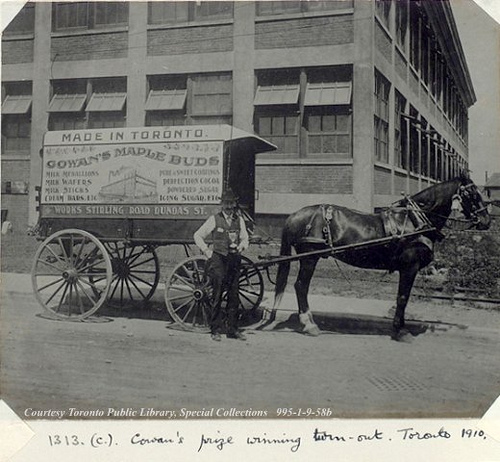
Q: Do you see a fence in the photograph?
A: No, there are no fences.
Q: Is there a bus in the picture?
A: No, there are no buses.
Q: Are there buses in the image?
A: No, there are no buses.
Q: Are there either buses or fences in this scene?
A: No, there are no buses or fences.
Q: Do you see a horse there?
A: Yes, there is a horse.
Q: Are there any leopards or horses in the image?
A: Yes, there is a horse.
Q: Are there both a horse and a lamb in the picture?
A: No, there is a horse but no lambs.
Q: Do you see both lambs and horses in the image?
A: No, there is a horse but no lambs.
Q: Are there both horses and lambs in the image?
A: No, there is a horse but no lambs.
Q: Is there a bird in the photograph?
A: No, there are no birds.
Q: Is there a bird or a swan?
A: No, there are no birds or swans.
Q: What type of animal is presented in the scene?
A: The animal is a horse.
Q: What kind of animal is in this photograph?
A: The animal is a horse.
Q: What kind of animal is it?
A: The animal is a horse.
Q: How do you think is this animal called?
A: This is a horse.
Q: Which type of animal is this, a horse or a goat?
A: This is a horse.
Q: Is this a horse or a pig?
A: This is a horse.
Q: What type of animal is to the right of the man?
A: The animal is a horse.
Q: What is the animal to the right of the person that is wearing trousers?
A: The animal is a horse.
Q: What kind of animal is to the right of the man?
A: The animal is a horse.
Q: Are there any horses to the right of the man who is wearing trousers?
A: Yes, there is a horse to the right of the man.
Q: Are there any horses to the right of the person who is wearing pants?
A: Yes, there is a horse to the right of the man.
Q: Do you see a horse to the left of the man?
A: No, the horse is to the right of the man.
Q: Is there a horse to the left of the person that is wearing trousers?
A: No, the horse is to the right of the man.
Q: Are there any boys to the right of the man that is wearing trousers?
A: No, there is a horse to the right of the man.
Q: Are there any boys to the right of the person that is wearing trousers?
A: No, there is a horse to the right of the man.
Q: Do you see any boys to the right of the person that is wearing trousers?
A: No, there is a horse to the right of the man.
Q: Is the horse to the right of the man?
A: Yes, the horse is to the right of the man.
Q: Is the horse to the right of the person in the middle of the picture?
A: Yes, the horse is to the right of the man.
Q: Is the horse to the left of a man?
A: No, the horse is to the right of a man.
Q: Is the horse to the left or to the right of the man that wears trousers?
A: The horse is to the right of the man.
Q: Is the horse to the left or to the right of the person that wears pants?
A: The horse is to the right of the man.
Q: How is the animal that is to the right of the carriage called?
A: The animal is a horse.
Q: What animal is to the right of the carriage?
A: The animal is a horse.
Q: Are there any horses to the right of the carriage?
A: Yes, there is a horse to the right of the carriage.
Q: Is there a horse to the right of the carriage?
A: Yes, there is a horse to the right of the carriage.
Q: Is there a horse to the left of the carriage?
A: No, the horse is to the right of the carriage.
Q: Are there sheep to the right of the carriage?
A: No, there is a horse to the right of the carriage.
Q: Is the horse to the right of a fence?
A: No, the horse is to the right of a carriage.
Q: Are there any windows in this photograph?
A: Yes, there is a window.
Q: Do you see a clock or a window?
A: Yes, there is a window.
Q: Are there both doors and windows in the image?
A: No, there is a window but no doors.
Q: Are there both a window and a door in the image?
A: No, there is a window but no doors.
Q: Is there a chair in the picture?
A: No, there are no chairs.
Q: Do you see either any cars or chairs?
A: No, there are no chairs or cars.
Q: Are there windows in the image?
A: Yes, there is a window.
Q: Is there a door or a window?
A: Yes, there is a window.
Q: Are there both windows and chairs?
A: No, there is a window but no chairs.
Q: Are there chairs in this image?
A: No, there are no chairs.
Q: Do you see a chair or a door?
A: No, there are no chairs or doors.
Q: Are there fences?
A: No, there are no fences.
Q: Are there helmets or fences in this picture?
A: No, there are no fences or helmets.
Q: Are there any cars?
A: No, there are no cars.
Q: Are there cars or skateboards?
A: No, there are no cars or skateboards.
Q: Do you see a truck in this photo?
A: No, there are no trucks.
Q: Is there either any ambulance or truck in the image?
A: No, there are no trucks or ambulances.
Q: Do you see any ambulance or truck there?
A: No, there are no trucks or ambulances.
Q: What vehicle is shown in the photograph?
A: The vehicle is a carriage.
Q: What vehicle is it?
A: The vehicle is a carriage.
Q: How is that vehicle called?
A: This is a carriage.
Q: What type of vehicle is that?
A: This is a carriage.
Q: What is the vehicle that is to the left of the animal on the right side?
A: The vehicle is a carriage.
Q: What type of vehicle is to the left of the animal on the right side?
A: The vehicle is a carriage.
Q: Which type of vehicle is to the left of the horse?
A: The vehicle is a carriage.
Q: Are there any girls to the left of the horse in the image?
A: No, there is a carriage to the left of the horse.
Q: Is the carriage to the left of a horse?
A: Yes, the carriage is to the left of a horse.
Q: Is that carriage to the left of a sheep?
A: No, the carriage is to the left of a horse.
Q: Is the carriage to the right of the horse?
A: No, the carriage is to the left of the horse.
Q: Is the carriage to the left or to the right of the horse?
A: The carriage is to the left of the horse.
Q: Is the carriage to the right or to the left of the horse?
A: The carriage is to the left of the horse.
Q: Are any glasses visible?
A: No, there are no glasses.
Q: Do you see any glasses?
A: No, there are no glasses.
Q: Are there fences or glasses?
A: No, there are no glasses or fences.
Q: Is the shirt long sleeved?
A: Yes, the shirt is long sleeved.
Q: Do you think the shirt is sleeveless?
A: No, the shirt is long sleeved.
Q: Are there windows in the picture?
A: Yes, there is a window.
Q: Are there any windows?
A: Yes, there is a window.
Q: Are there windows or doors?
A: Yes, there is a window.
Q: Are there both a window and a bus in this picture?
A: No, there is a window but no buses.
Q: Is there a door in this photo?
A: No, there are no doors.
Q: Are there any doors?
A: No, there are no doors.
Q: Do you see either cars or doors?
A: No, there are no doors or cars.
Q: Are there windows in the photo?
A: Yes, there is a window.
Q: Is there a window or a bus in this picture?
A: Yes, there is a window.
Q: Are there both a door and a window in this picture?
A: No, there is a window but no doors.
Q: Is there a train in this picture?
A: No, there are no trains.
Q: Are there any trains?
A: No, there are no trains.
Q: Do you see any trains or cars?
A: No, there are no trains or cars.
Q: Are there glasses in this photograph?
A: No, there are no glasses.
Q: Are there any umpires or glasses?
A: No, there are no glasses or umpires.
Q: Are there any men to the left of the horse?
A: Yes, there is a man to the left of the horse.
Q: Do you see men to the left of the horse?
A: Yes, there is a man to the left of the horse.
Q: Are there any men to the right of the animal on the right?
A: No, the man is to the left of the horse.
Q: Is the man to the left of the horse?
A: Yes, the man is to the left of the horse.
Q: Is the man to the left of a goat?
A: No, the man is to the left of the horse.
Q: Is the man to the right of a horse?
A: No, the man is to the left of a horse.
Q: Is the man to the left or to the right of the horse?
A: The man is to the left of the horse.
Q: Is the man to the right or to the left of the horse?
A: The man is to the left of the horse.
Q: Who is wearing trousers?
A: The man is wearing trousers.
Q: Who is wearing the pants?
A: The man is wearing trousers.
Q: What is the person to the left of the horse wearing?
A: The man is wearing trousers.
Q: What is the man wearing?
A: The man is wearing trousers.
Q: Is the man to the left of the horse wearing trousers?
A: Yes, the man is wearing trousers.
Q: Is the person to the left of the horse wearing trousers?
A: Yes, the man is wearing trousers.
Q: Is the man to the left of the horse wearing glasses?
A: No, the man is wearing trousers.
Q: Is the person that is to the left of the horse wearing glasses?
A: No, the man is wearing trousers.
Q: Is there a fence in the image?
A: No, there are no fences.